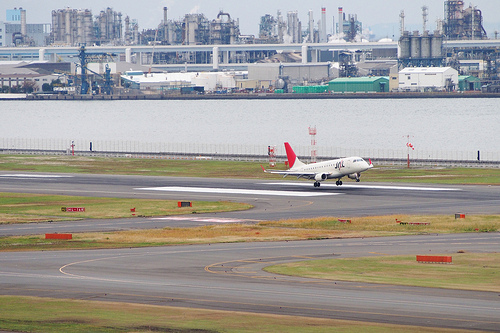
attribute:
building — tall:
[160, 3, 171, 24]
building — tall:
[305, 8, 315, 31]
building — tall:
[319, 6, 329, 40]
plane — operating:
[263, 145, 374, 185]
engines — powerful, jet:
[313, 170, 334, 183]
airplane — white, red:
[259, 141, 376, 189]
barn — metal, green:
[326, 71, 389, 94]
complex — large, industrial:
[2, 0, 484, 100]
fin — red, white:
[281, 138, 305, 170]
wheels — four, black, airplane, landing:
[311, 175, 345, 188]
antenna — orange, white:
[305, 121, 320, 162]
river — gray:
[4, 96, 484, 160]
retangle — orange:
[412, 246, 447, 265]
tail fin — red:
[274, 151, 306, 189]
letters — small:
[326, 170, 357, 172]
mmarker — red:
[400, 246, 447, 276]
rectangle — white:
[131, 165, 325, 208]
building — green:
[325, 67, 399, 86]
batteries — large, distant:
[396, 27, 465, 68]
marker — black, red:
[178, 200, 194, 217]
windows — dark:
[345, 159, 365, 165]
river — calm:
[62, 90, 496, 149]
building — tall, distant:
[63, 11, 90, 49]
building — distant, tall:
[68, 11, 97, 61]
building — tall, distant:
[65, 9, 90, 34]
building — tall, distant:
[107, 16, 147, 42]